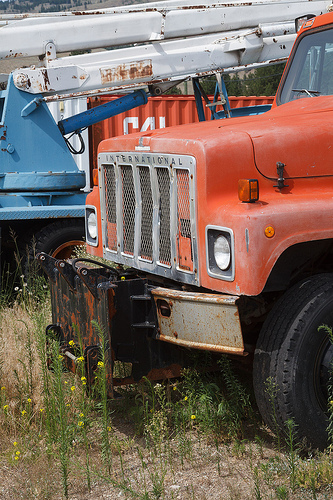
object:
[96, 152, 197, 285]
window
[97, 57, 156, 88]
rust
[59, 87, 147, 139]
shock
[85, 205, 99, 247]
front headlight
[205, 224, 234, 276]
front headlight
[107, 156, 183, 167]
letters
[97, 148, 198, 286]
front grill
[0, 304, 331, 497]
ground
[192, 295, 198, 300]
spots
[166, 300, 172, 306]
spots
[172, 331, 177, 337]
spots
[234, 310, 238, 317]
spots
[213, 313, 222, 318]
spots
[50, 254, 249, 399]
bumper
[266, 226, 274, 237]
light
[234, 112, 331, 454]
side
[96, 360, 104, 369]
flowers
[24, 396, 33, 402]
flowers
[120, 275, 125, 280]
flowers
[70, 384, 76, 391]
flowers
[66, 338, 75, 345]
flowers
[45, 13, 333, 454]
jeep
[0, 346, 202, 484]
weeds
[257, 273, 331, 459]
jeepwheel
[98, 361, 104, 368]
flower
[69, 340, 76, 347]
flower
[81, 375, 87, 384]
flower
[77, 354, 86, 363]
flower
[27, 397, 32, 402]
flower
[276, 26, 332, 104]
windshield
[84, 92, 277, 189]
trailer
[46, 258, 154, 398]
machinery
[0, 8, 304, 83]
machinery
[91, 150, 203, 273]
grate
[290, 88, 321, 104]
wiper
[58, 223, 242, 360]
part